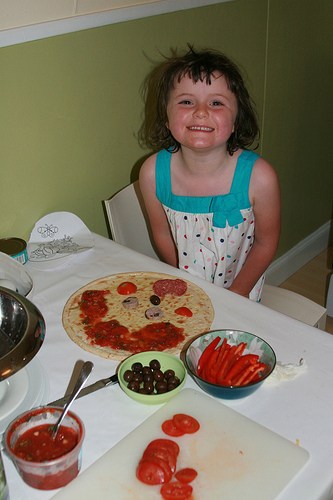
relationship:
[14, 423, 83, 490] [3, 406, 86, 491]
salsa in a container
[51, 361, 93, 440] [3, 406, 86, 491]
spoon in container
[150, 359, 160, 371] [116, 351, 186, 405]
olive in bowl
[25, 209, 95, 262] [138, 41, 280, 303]
paper near girl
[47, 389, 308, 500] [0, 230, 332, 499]
cutting board on table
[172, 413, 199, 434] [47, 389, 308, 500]
tomato on cutting board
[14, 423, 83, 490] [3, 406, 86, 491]
salsa in container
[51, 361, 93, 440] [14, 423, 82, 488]
spoon in salsa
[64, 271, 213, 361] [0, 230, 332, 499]
dough on table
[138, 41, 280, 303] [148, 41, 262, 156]
girl has hair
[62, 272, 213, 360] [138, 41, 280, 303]
pizza in front of girl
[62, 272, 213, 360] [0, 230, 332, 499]
pizza on table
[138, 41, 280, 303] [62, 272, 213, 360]
girl making a pizza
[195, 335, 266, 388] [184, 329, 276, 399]
bell peppers in bowl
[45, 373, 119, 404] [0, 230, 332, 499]
knife on table